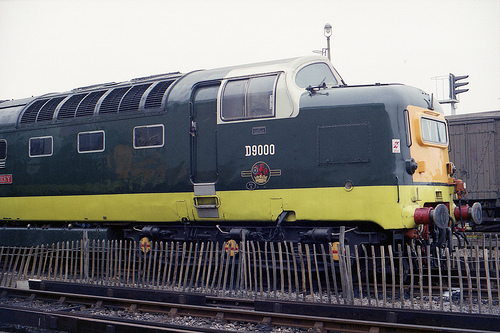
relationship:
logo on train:
[230, 137, 290, 183] [51, 60, 486, 297]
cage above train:
[425, 68, 489, 107] [1, 54, 491, 285]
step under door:
[176, 177, 236, 221] [170, 77, 236, 169]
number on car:
[244, 144, 275, 157] [62, 50, 484, 270]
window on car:
[56, 52, 480, 252] [206, 70, 284, 121]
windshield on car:
[292, 60, 338, 89] [97, 43, 486, 263]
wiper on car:
[304, 76, 329, 95] [67, 70, 435, 222]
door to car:
[189, 79, 233, 183] [6, 54, 485, 252]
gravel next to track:
[15, 292, 144, 322] [7, 280, 495, 330]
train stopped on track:
[1, 54, 491, 285] [2, 226, 499, 328]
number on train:
[244, 144, 275, 157] [1, 54, 491, 285]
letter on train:
[236, 141, 253, 168] [1, 54, 491, 285]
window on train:
[131, 123, 171, 153] [1, 54, 491, 285]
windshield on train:
[292, 60, 338, 89] [1, 54, 491, 285]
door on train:
[187, 79, 220, 183] [1, 54, 491, 285]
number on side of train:
[244, 143, 290, 166] [1, 54, 491, 285]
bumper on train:
[410, 194, 460, 231] [1, 54, 491, 285]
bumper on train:
[454, 190, 494, 233] [1, 54, 491, 285]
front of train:
[403, 101, 474, 197] [1, 54, 491, 285]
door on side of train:
[187, 79, 220, 183] [1, 54, 491, 285]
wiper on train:
[303, 75, 333, 111] [1, 54, 491, 285]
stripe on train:
[1, 180, 453, 235] [1, 54, 491, 285]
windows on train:
[21, 119, 178, 157] [1, 54, 491, 285]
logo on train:
[240, 160, 281, 190] [13, 47, 483, 262]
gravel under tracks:
[0, 294, 294, 333] [59, 289, 161, 330]